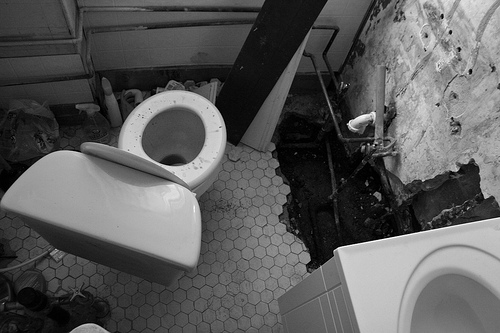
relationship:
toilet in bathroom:
[0, 89, 230, 289] [2, 0, 499, 330]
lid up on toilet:
[77, 140, 189, 187] [0, 89, 230, 289]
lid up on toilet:
[75, 130, 188, 187] [0, 89, 230, 289]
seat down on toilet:
[124, 84, 226, 184] [0, 89, 230, 289]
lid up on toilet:
[77, 140, 189, 187] [6, 97, 243, 271]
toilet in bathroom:
[6, 97, 243, 271] [2, 0, 499, 330]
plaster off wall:
[297, 5, 358, 74] [340, 0, 498, 210]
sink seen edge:
[413, 276, 499, 331] [417, 276, 429, 283]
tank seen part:
[0, 148, 206, 288] [139, 222, 157, 236]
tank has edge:
[0, 90, 232, 297] [141, 251, 168, 265]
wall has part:
[336, 0, 498, 247] [448, 178, 466, 196]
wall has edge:
[336, 0, 498, 247] [442, 60, 462, 89]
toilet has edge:
[0, 89, 230, 289] [190, 202, 202, 232]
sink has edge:
[275, 216, 499, 333] [326, 234, 351, 268]